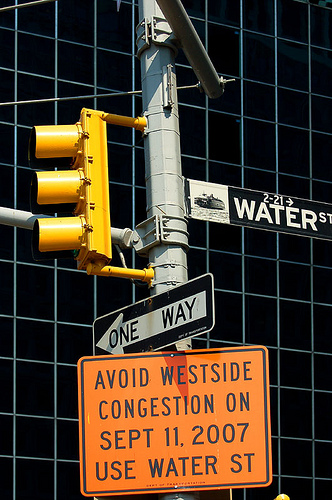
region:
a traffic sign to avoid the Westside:
[75, 344, 272, 497]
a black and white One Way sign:
[91, 273, 216, 355]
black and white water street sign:
[185, 176, 330, 240]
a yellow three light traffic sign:
[27, 105, 156, 283]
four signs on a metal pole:
[28, 106, 330, 497]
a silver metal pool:
[135, 1, 185, 276]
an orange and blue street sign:
[77, 345, 273, 497]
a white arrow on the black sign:
[95, 289, 207, 354]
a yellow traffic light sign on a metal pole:
[31, 106, 176, 283]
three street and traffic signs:
[77, 177, 330, 497]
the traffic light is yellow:
[5, 89, 151, 289]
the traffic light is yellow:
[15, 92, 140, 310]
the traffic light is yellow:
[29, 99, 128, 298]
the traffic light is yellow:
[18, 105, 148, 292]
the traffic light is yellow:
[18, 91, 121, 301]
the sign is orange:
[56, 342, 287, 497]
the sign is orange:
[59, 331, 270, 498]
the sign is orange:
[61, 345, 282, 494]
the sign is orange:
[59, 349, 291, 497]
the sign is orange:
[59, 346, 281, 498]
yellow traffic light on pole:
[32, 112, 120, 293]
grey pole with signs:
[139, 69, 206, 295]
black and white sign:
[99, 277, 201, 355]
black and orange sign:
[86, 358, 270, 481]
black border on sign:
[71, 351, 263, 480]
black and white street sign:
[209, 175, 328, 220]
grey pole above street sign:
[154, 1, 240, 110]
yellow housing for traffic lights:
[48, 105, 121, 279]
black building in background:
[213, 45, 331, 176]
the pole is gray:
[124, 99, 195, 346]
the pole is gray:
[133, 120, 186, 316]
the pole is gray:
[117, 105, 194, 374]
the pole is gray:
[132, 123, 187, 247]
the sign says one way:
[86, 279, 205, 364]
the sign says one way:
[77, 288, 232, 360]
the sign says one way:
[86, 292, 236, 368]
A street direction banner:
[183, 172, 320, 237]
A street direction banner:
[95, 313, 210, 348]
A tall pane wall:
[268, 346, 325, 498]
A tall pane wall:
[229, 245, 323, 331]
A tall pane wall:
[190, 97, 309, 169]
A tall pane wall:
[12, 16, 156, 114]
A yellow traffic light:
[26, 100, 157, 288]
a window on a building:
[13, 456, 54, 497]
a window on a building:
[12, 412, 55, 460]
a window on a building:
[16, 265, 52, 321]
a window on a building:
[13, 315, 57, 362]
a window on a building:
[13, 358, 56, 416]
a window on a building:
[57, 268, 94, 325]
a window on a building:
[212, 285, 244, 342]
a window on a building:
[239, 291, 275, 344]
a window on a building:
[278, 297, 313, 354]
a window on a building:
[276, 346, 311, 387]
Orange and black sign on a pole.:
[74, 348, 275, 499]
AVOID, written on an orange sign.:
[90, 363, 156, 392]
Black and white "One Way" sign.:
[85, 281, 221, 352]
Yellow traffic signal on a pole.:
[16, 99, 154, 298]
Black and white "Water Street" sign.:
[183, 166, 330, 245]